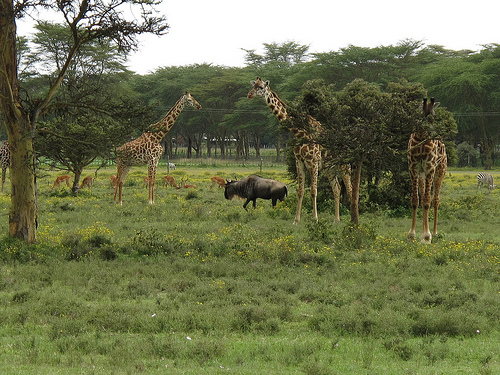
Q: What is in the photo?
A: Giraffes.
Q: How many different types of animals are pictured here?
A: Three.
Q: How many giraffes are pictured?
A: Three.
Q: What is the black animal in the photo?
A: Buffalo.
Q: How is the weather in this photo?
A: Overcast.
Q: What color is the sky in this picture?
A: White.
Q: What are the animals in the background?
A: Antelopes.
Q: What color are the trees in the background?
A: Green.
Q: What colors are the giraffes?
A: Brown and yellow.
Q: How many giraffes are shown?
A: 4.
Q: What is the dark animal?
A: A wildabeast.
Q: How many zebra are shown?
A: One.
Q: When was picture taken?
A: During the daytime.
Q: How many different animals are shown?
A: 4.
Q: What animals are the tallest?
A: Giraffes.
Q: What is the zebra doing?
A: Grazing.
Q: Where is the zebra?
A: On the right.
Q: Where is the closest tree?
A: On the left.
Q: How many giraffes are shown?
A: 3.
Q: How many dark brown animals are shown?
A: 1.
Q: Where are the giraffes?
A: On grass.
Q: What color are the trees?
A: Green.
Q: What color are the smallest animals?
A: Light brown.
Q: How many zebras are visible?
A: 1.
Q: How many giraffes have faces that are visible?
A: 2.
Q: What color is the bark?
A: Brown.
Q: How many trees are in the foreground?
A: 2.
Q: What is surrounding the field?
A: Trees.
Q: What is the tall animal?
A: Giraffe.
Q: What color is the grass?
A: Green.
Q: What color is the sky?
A: Gray.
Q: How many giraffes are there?
A: Three.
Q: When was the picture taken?
A: Daytime.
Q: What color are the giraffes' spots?
A: Brown.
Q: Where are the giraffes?
A: On the grass.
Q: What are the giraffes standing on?
A: Grass.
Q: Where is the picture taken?
A: In a field.